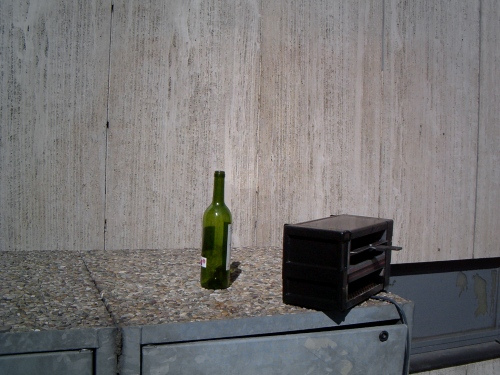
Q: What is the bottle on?
A: A counter.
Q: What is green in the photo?
A: A bottle.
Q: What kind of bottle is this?
A: Wine.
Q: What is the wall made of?
A: Wood.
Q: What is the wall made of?
A: Wood.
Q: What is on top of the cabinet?
A: Bottle.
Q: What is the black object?
A: Toaster.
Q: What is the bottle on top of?
A: Cabinet.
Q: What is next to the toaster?
A: Bottle.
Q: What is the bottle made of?
A: Glass.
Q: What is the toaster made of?
A: Metal.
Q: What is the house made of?
A: Wood.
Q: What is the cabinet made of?
A: Stone.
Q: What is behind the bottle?
A: Wall.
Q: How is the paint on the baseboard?
A: Falling off.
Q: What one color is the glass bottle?
A: Green.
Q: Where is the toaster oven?
A: On the table.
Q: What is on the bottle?
A: A label.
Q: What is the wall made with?
A: Wood.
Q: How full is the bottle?
A: Empty.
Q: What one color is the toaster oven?
A: Black.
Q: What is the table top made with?
A: Stone.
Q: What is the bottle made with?
A: Glass.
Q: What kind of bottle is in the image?
A: A wine bottle.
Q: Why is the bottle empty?
A: The wine was consumed.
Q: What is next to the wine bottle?
A: A black toaster.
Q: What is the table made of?
A: Ceramics.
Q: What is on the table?
A: Bottle.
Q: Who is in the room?
A: No one.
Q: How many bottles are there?
A: 1.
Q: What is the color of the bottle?
A: Green.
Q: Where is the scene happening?
A: On a city street.